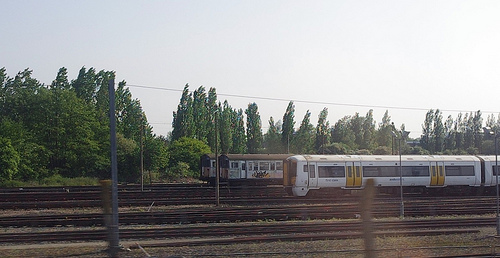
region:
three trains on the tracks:
[201, 140, 496, 205]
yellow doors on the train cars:
[342, 160, 444, 190]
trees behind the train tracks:
[2, 67, 497, 189]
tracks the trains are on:
[0, 164, 290, 207]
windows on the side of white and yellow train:
[303, 162, 498, 176]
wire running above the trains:
[33, 71, 499, 117]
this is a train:
[279, 146, 499, 203]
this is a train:
[218, 145, 290, 181]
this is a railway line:
[143, 221, 243, 237]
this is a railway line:
[122, 200, 497, 223]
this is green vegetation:
[1, 68, 53, 181]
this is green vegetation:
[55, 69, 110, 189]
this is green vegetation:
[115, 82, 165, 180]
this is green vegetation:
[282, 102, 404, 149]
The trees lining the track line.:
[1, 66, 496, 191]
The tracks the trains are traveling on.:
[2, 185, 497, 235]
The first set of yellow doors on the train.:
[343, 158, 362, 186]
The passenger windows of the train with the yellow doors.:
[308, 161, 479, 178]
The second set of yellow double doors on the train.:
[428, 163, 443, 185]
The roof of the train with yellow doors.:
[291, 154, 499, 166]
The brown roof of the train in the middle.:
[219, 148, 301, 160]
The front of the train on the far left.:
[201, 155, 216, 182]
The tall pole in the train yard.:
[100, 71, 126, 256]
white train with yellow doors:
[280, 152, 498, 198]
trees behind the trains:
[4, 64, 489, 183]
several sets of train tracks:
[10, 163, 491, 257]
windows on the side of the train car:
[303, 161, 473, 181]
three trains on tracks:
[197, 149, 499, 203]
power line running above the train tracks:
[2, 73, 499, 116]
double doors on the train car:
[343, 161, 444, 188]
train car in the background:
[194, 146, 218, 181]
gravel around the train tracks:
[8, 182, 481, 257]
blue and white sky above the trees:
[1, 5, 496, 131]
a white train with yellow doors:
[281, 152, 497, 193]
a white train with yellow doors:
[216, 153, 287, 186]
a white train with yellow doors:
[201, 153, 219, 180]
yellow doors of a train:
[343, 163, 361, 189]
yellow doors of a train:
[429, 161, 444, 186]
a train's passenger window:
[318, 166, 345, 178]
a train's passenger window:
[362, 164, 431, 177]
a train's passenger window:
[445, 166, 475, 176]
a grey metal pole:
[110, 73, 117, 256]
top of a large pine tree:
[172, 83, 191, 139]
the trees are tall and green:
[0, 63, 499, 185]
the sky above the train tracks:
[0, 0, 497, 257]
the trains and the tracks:
[1, 150, 497, 256]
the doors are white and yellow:
[343, 159, 361, 188]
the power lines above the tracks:
[1, 76, 498, 256]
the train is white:
[283, 151, 498, 199]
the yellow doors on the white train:
[282, 152, 498, 201]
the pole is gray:
[105, 75, 122, 257]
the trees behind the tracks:
[1, 65, 498, 256]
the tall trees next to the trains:
[0, 66, 499, 198]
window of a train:
[230, 160, 238, 167]